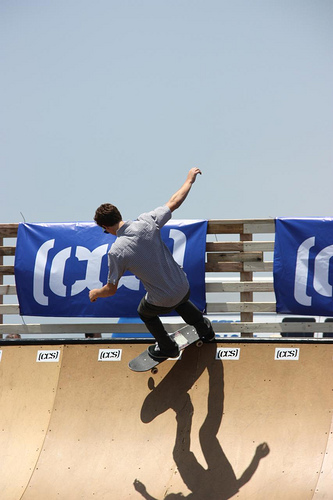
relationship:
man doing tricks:
[63, 169, 225, 353] [160, 331, 230, 352]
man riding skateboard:
[63, 169, 225, 353] [123, 313, 241, 374]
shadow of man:
[133, 362, 261, 488] [63, 169, 225, 353]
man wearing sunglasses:
[63, 169, 225, 353] [96, 226, 110, 236]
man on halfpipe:
[63, 169, 225, 353] [0, 330, 332, 498]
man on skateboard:
[63, 169, 225, 353] [123, 313, 241, 374]